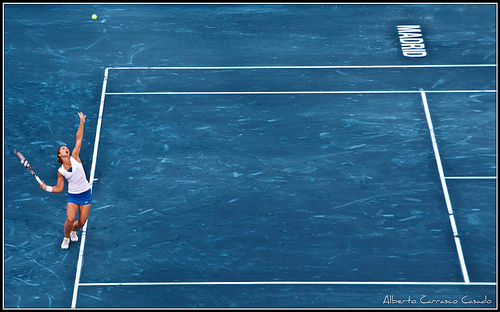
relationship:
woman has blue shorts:
[12, 108, 97, 249] [66, 188, 93, 205]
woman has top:
[12, 111, 97, 250] [55, 154, 90, 194]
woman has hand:
[12, 111, 97, 250] [73, 107, 92, 123]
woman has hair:
[12, 111, 97, 250] [56, 142, 61, 164]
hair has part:
[56, 142, 61, 164] [54, 148, 61, 153]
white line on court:
[416, 87, 473, 282] [69, 61, 499, 306]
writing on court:
[397, 19, 427, 63] [71, 63, 500, 307]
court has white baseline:
[27, 41, 483, 309] [70, 63, 118, 308]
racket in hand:
[13, 149, 46, 188] [34, 174, 43, 184]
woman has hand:
[12, 111, 97, 250] [34, 174, 43, 184]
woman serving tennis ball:
[12, 111, 97, 250] [89, 8, 99, 24]